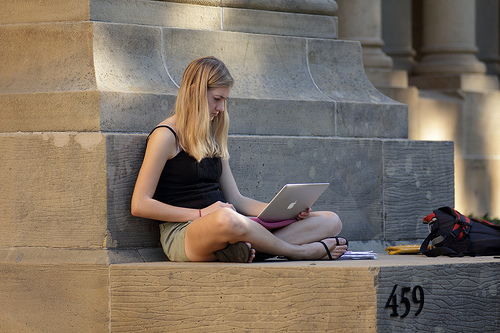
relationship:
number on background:
[386, 277, 429, 321] [0, 0, 499, 333]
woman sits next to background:
[129, 59, 249, 259] [0, 0, 499, 333]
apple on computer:
[289, 200, 296, 209] [246, 182, 331, 223]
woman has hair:
[129, 59, 249, 259] [188, 58, 211, 138]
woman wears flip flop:
[129, 59, 249, 259] [213, 241, 251, 263]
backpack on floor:
[426, 203, 490, 256] [377, 255, 449, 272]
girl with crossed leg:
[129, 59, 249, 259] [189, 206, 343, 261]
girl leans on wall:
[129, 59, 249, 259] [240, 143, 300, 177]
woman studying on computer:
[129, 59, 249, 259] [246, 182, 331, 223]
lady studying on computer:
[129, 59, 249, 259] [246, 182, 331, 223]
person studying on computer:
[129, 59, 249, 259] [246, 182, 331, 223]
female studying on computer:
[129, 59, 249, 259] [268, 180, 314, 220]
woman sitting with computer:
[129, 59, 249, 259] [268, 180, 314, 220]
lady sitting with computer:
[129, 59, 249, 259] [268, 180, 314, 220]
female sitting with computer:
[129, 59, 249, 259] [268, 180, 314, 220]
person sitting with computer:
[129, 59, 249, 259] [268, 180, 314, 220]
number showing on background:
[386, 277, 429, 321] [0, 0, 499, 333]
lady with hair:
[129, 59, 249, 259] [188, 58, 211, 138]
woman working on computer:
[129, 59, 249, 259] [246, 182, 331, 223]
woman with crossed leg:
[129, 59, 249, 259] [189, 206, 343, 261]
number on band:
[386, 277, 429, 321] [199, 209, 202, 218]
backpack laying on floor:
[426, 203, 490, 256] [109, 255, 500, 272]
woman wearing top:
[129, 59, 249, 259] [156, 150, 221, 204]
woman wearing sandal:
[129, 59, 249, 259] [213, 243, 256, 267]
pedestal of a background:
[420, 8, 486, 76] [0, 0, 499, 333]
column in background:
[420, 8, 486, 76] [483, 7, 496, 44]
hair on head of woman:
[188, 58, 211, 138] [129, 59, 249, 259]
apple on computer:
[286, 200, 297, 210] [268, 180, 314, 220]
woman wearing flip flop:
[129, 59, 249, 259] [213, 243, 256, 267]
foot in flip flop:
[219, 243, 258, 260] [213, 241, 251, 263]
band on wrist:
[196, 209, 207, 218] [202, 206, 213, 215]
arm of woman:
[147, 131, 162, 220] [129, 59, 249, 259]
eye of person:
[209, 91, 225, 104] [129, 59, 249, 259]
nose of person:
[217, 103, 225, 112] [129, 59, 249, 259]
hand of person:
[203, 197, 236, 216] [129, 59, 249, 259]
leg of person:
[189, 220, 255, 238] [129, 59, 249, 259]